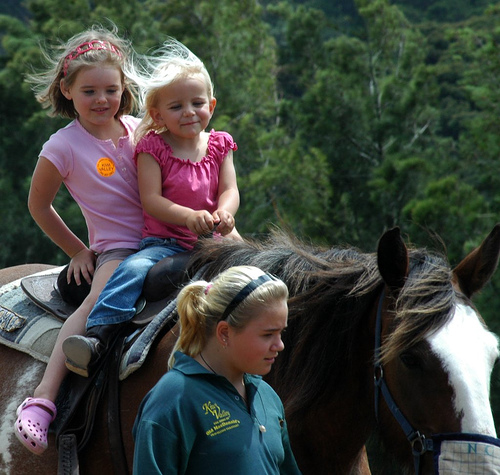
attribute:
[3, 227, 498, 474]
horse — brown, white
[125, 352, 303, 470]
shirt — green, polo, blue-green, teal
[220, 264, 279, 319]
headband — black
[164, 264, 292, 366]
hair — blonde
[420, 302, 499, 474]
face — white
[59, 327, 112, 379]
shoes — black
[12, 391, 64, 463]
shoes — pink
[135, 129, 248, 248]
shirt — pink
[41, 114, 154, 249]
shirt — pink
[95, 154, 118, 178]
sticker — yellow, orange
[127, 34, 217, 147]
hair — blown, blonde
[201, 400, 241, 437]
writing — yellow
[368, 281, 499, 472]
harness — black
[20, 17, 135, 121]
hair — brown